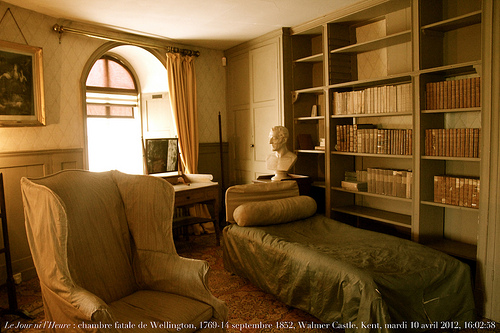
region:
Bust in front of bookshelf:
[262, 122, 299, 181]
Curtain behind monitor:
[164, 50, 203, 177]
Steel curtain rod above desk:
[50, 20, 202, 57]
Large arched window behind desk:
[83, 50, 145, 170]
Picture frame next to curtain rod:
[0, 5, 47, 127]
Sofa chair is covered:
[17, 167, 226, 332]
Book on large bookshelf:
[338, 177, 368, 191]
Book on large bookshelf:
[402, 170, 412, 195]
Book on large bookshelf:
[422, 123, 431, 155]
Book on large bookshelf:
[430, 173, 440, 203]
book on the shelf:
[437, 127, 443, 155]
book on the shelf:
[436, 174, 440, 201]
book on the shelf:
[447, 175, 454, 206]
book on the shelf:
[473, 180, 480, 207]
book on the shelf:
[460, 170, 472, 207]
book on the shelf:
[460, 130, 462, 161]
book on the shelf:
[363, 130, 369, 153]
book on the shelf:
[351, 123, 352, 149]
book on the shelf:
[341, 123, 350, 152]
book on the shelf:
[394, 82, 400, 113]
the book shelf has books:
[278, 56, 475, 226]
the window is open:
[80, 56, 200, 175]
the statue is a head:
[252, 119, 307, 169]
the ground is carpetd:
[219, 271, 278, 332]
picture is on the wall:
[8, 38, 67, 145]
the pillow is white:
[233, 201, 333, 234]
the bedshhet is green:
[276, 237, 456, 309]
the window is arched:
[89, 56, 166, 97]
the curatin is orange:
[169, 56, 221, 188]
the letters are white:
[34, 313, 493, 332]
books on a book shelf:
[329, 84, 421, 114]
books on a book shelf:
[423, 76, 493, 105]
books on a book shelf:
[421, 124, 486, 156]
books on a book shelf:
[428, 175, 490, 210]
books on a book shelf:
[333, 125, 419, 158]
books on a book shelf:
[337, 161, 416, 197]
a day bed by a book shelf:
[229, 183, 445, 324]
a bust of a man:
[253, 119, 295, 181]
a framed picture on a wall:
[0, 35, 49, 132]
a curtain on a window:
[172, 45, 204, 172]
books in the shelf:
[333, 88, 363, 118]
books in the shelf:
[330, 124, 370, 153]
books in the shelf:
[423, 164, 464, 201]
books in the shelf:
[431, 130, 492, 168]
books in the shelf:
[346, 173, 411, 201]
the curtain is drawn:
[151, 43, 210, 173]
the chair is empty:
[28, 160, 178, 323]